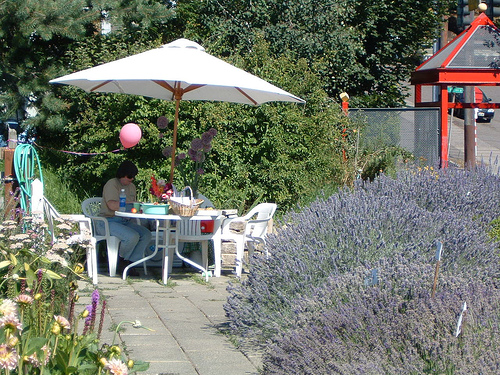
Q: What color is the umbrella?
A: White.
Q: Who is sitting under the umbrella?
A: A woman.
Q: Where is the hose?
A: Hanging by the table.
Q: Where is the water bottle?
A: On the table.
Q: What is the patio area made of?
A: Block.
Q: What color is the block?
A: Gray.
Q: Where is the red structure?
A: To the right of the table.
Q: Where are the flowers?
A: In the front of the photo.